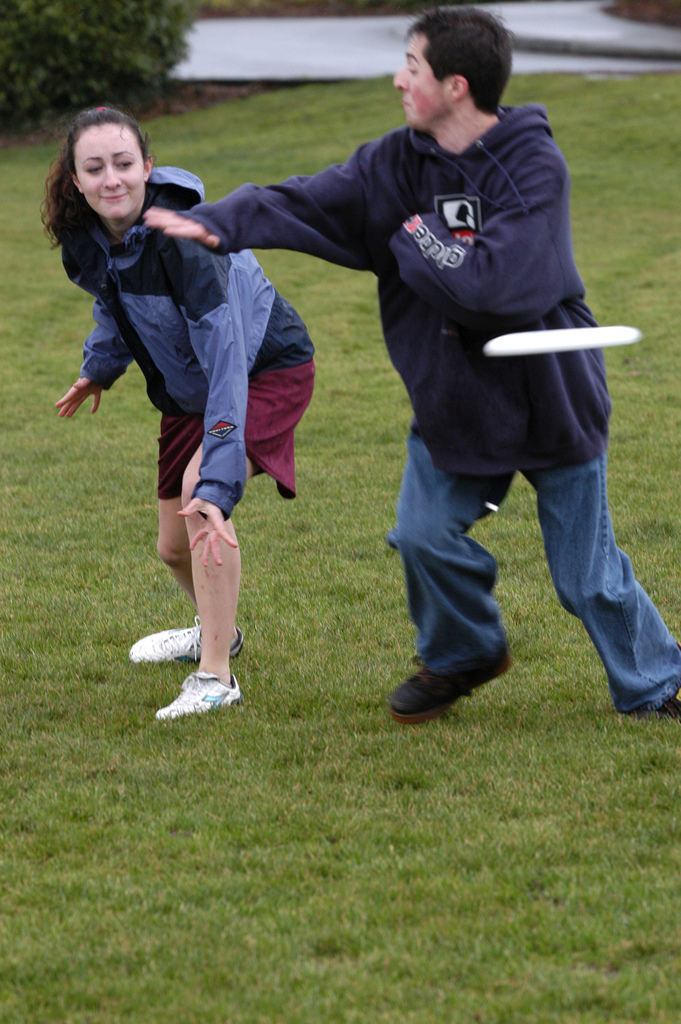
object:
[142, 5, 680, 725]
man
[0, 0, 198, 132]
bush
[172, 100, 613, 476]
hoodie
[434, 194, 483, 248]
loogo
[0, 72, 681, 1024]
grass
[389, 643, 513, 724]
shoe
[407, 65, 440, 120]
cheeks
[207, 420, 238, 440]
label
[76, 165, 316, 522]
jacket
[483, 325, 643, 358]
disc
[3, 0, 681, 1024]
park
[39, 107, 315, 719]
girl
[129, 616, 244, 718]
shoes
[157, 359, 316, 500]
shorts